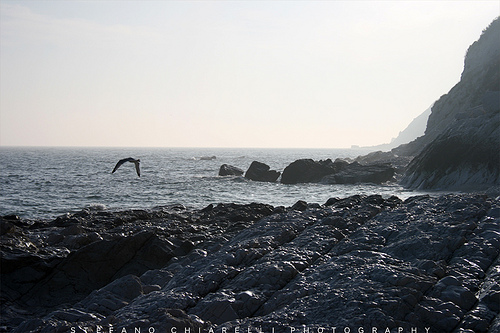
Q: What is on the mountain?
A: Rock.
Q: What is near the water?
A: Rocks.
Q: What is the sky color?
A: Pink.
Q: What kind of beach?
A: Rocky.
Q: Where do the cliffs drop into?
A: Sea.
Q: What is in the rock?
A: Cravvesses.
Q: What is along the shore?
A: Mountains.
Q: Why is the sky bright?
A: Sunrise is occuring.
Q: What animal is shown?
A: A bird.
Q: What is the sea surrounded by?
A: Rocks and hilltops.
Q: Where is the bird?
A: Close to the rocky shore.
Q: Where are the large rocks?
A: In the water.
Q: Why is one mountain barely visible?
A: It's distant from the shore.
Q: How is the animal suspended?
A: It can fly.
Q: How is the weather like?
A: Sunny.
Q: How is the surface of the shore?
A: Bumpy and not smooth.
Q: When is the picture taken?
A: Daytime.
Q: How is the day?
A: Cloudy.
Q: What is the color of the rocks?
A: Grey.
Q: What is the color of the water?
A: Blue.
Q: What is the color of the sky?
A: White.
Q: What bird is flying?
A: Crane.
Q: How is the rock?
A: Wet.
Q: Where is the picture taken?
A: The seaside.